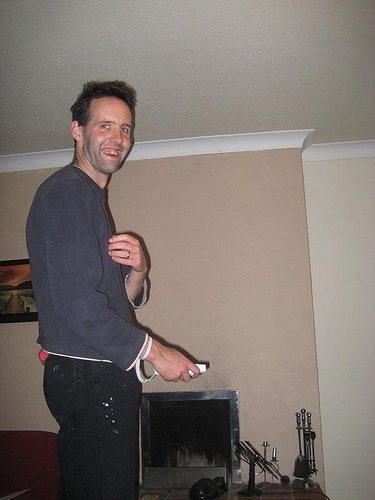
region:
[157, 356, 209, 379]
the man holds a remote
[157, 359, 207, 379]
the remote is white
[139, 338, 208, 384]
the remote is attached to his wrist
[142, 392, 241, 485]
the fireplace is off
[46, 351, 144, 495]
the man wears black pants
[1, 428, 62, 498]
the couch is red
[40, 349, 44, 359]
the man has a red object on his back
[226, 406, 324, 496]
objects are on the floor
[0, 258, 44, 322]
a painting is on the wall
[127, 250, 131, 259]
the man wears a ring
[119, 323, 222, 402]
white wii remote strapped to hand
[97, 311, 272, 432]
white wii remote strapped to hand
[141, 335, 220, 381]
white wii remote strapped to hand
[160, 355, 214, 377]
white Wii remote in man's hands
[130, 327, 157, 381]
white wrist strap of the Wii remote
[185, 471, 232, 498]
black headphones on table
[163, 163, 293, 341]
tan colored wall in room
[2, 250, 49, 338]
framed painting on the wall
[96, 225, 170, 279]
left hand of man playing Wii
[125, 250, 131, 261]
wedding band of the man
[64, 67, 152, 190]
face of the man playing Wii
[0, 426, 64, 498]
red sofa by the wall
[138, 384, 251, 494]
silver framed fireplace on the wall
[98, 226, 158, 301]
A man's hand with a wedding band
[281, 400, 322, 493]
Fireplace tools set on a hearth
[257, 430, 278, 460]
A candleabra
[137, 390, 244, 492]
A black fireplace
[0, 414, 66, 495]
A red chair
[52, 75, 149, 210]
A man smiling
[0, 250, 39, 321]
A picture on a wall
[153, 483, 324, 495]
A red brick hearth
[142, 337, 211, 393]
A hand holding a white game controller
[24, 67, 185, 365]
A man in a grey shirt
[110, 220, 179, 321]
man wearing wedding ring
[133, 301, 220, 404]
man holding Wii controller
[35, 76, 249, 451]
man wearing long sleeve shirt and black jeans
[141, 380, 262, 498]
fireplace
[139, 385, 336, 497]
fireplace and fireplace tools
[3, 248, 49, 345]
picture hanging on wall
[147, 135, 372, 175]
white decorative molding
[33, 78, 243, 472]
man standing in room holding wii controller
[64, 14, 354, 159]
white ceiling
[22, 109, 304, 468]
man standing in room in house playing video game